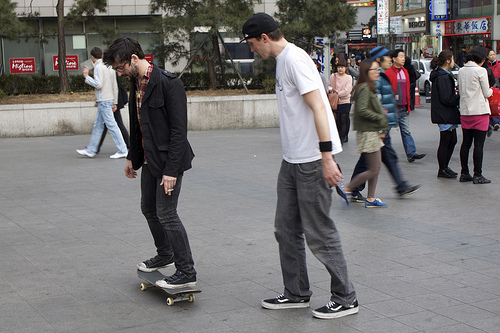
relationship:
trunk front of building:
[50, 0, 78, 97] [2, 0, 283, 92]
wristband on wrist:
[316, 140, 334, 153] [314, 129, 336, 166]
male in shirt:
[235, 10, 360, 322] [269, 45, 339, 160]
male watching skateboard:
[229, 10, 385, 328] [126, 247, 203, 309]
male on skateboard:
[102, 36, 197, 288] [134, 264, 203, 306]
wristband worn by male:
[316, 138, 334, 153] [237, 8, 362, 321]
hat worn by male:
[232, 14, 290, 49] [245, 23, 390, 301]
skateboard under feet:
[118, 257, 205, 316] [124, 245, 196, 286]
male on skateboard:
[102, 36, 201, 292] [127, 251, 209, 318]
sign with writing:
[440, 15, 498, 39] [453, 17, 490, 35]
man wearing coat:
[384, 49, 425, 160] [385, 65, 412, 115]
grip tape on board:
[139, 268, 195, 295] [131, 256, 214, 311]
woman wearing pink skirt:
[455, 48, 495, 184] [459, 115, 489, 132]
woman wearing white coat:
[455, 48, 495, 184] [455, 61, 489, 113]